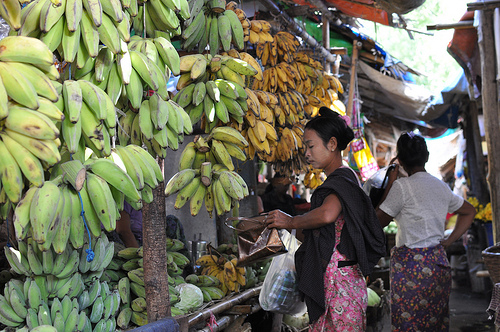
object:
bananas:
[84, 157, 144, 202]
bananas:
[250, 119, 269, 144]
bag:
[257, 228, 304, 314]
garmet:
[307, 217, 370, 332]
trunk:
[140, 160, 176, 326]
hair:
[303, 105, 355, 150]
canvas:
[334, 0, 366, 26]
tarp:
[343, 22, 416, 84]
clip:
[336, 114, 351, 128]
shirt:
[378, 171, 465, 249]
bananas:
[90, 296, 106, 323]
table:
[127, 284, 270, 332]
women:
[259, 102, 370, 332]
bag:
[225, 213, 289, 265]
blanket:
[293, 166, 385, 323]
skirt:
[390, 245, 452, 332]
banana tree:
[139, 102, 182, 317]